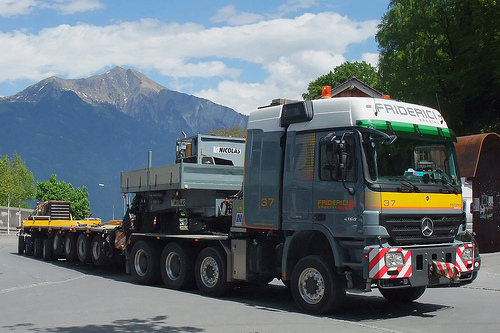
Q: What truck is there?
A: 18 wheeler.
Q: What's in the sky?
A: Clouds.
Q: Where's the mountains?
A: Background.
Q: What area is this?
A: Rural.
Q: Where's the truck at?
A: On road.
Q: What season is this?
A: Summer.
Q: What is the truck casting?
A: Shadow.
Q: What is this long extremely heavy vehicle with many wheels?
A: Semi truck.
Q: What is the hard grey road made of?
A: Asphalt.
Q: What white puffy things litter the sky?
A: Clouds.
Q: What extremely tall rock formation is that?
A: Mountain.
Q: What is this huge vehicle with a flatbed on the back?
A: Truck.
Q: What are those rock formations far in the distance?
A: Mountains.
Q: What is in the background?
A: A mountain.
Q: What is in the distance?
A: A mountain.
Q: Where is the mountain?
A: In the distance.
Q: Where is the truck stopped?
A: On the road.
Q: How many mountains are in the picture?
A: One.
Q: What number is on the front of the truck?
A: Thirty-seven.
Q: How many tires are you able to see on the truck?
A: Thirteen.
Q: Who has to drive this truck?
A: A truck driver.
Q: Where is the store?
A: Behind the truck.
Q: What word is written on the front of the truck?
A: Friderici.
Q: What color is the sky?
A: Blue and white.